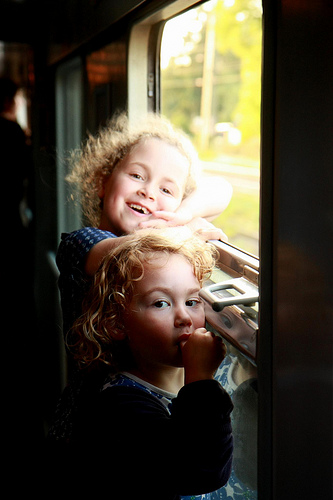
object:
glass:
[160, 2, 260, 259]